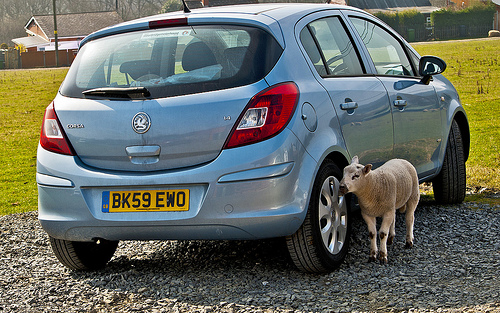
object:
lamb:
[338, 154, 417, 264]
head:
[338, 155, 373, 194]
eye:
[351, 172, 359, 179]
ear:
[360, 163, 372, 175]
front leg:
[377, 209, 394, 264]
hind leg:
[405, 188, 420, 248]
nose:
[339, 179, 347, 189]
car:
[35, 1, 470, 273]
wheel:
[285, 161, 353, 273]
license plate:
[102, 188, 190, 211]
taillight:
[224, 81, 301, 156]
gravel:
[0, 197, 500, 312]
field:
[0, 35, 499, 216]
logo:
[131, 111, 151, 134]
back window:
[61, 23, 284, 101]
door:
[294, 10, 392, 172]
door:
[338, 8, 443, 178]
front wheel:
[433, 117, 466, 206]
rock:
[189, 279, 270, 296]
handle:
[394, 98, 405, 106]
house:
[4, 10, 125, 68]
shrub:
[370, 4, 496, 43]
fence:
[21, 49, 78, 66]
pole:
[52, 0, 60, 68]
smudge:
[368, 230, 376, 241]